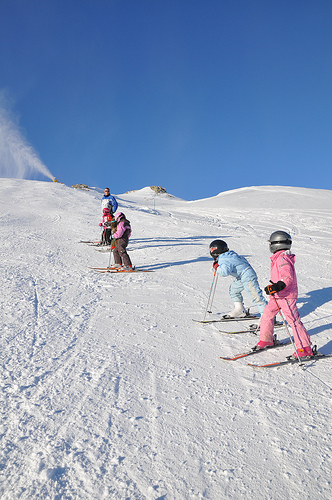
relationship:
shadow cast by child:
[134, 257, 215, 273] [108, 213, 133, 271]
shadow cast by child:
[278, 322, 331, 358] [250, 231, 316, 361]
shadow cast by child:
[295, 287, 331, 317] [208, 240, 270, 319]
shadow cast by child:
[126, 242, 205, 252] [100, 208, 116, 245]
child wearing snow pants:
[250, 231, 316, 361] [257, 296, 312, 347]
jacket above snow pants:
[266, 251, 298, 298] [257, 296, 312, 347]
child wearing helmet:
[250, 231, 316, 361] [269, 231, 292, 252]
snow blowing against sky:
[0, 93, 55, 183] [1, 0, 331, 201]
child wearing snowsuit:
[208, 240, 270, 319] [214, 251, 268, 320]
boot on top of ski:
[287, 346, 314, 360] [245, 353, 331, 367]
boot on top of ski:
[254, 343, 272, 352] [220, 342, 285, 363]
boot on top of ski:
[224, 303, 247, 319] [193, 317, 261, 325]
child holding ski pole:
[250, 231, 316, 361] [272, 291, 306, 372]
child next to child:
[208, 240, 270, 319] [250, 231, 316, 361]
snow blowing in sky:
[0, 93, 55, 183] [1, 0, 331, 201]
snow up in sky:
[0, 93, 55, 183] [1, 0, 331, 201]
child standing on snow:
[108, 213, 133, 271] [0, 180, 332, 499]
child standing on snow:
[250, 231, 316, 361] [0, 180, 332, 499]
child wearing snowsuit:
[250, 231, 316, 361] [260, 249, 313, 350]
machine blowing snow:
[53, 177, 60, 185] [0, 93, 55, 183]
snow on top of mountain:
[0, 180, 332, 499] [0, 179, 330, 500]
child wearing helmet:
[208, 240, 270, 319] [208, 240, 228, 257]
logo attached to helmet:
[208, 245, 217, 253] [208, 240, 228, 257]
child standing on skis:
[250, 231, 316, 361] [219, 339, 331, 368]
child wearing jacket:
[250, 231, 316, 361] [266, 251, 298, 298]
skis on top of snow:
[219, 339, 331, 368] [0, 180, 332, 499]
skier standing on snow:
[100, 185, 116, 215] [0, 180, 332, 499]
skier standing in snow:
[100, 185, 116, 215] [0, 180, 332, 499]